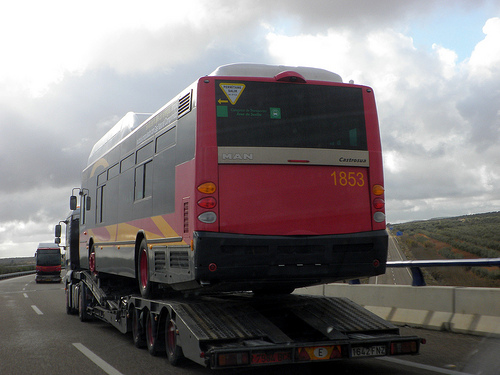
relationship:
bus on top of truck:
[70, 62, 389, 299] [53, 206, 425, 370]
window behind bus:
[213, 80, 369, 168] [70, 62, 389, 299]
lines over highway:
[21, 281, 124, 375] [0, 271, 499, 375]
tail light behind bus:
[196, 182, 217, 224] [70, 62, 389, 299]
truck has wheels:
[53, 206, 425, 370] [66, 282, 183, 367]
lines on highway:
[21, 281, 124, 375] [0, 271, 499, 375]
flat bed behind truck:
[76, 269, 426, 370] [53, 206, 425, 370]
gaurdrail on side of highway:
[291, 257, 500, 338] [0, 271, 499, 375]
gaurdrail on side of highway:
[385, 259, 499, 268] [0, 271, 499, 375]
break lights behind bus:
[371, 184, 384, 223] [70, 62, 389, 299]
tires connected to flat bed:
[131, 310, 180, 365] [76, 269, 426, 370]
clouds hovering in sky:
[0, 1, 499, 242] [0, 1, 498, 259]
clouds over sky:
[0, 1, 499, 242] [0, 1, 498, 259]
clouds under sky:
[0, 1, 499, 242] [0, 1, 498, 259]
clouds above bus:
[0, 1, 499, 242] [70, 62, 389, 299]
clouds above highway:
[0, 1, 499, 242] [0, 271, 499, 375]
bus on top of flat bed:
[70, 62, 389, 299] [76, 269, 426, 370]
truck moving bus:
[53, 206, 425, 370] [70, 62, 389, 299]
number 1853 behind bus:
[330, 170, 364, 189] [70, 62, 389, 299]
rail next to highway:
[386, 258, 498, 267] [0, 271, 499, 375]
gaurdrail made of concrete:
[291, 257, 500, 338] [291, 284, 499, 336]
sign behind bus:
[217, 82, 246, 105] [70, 62, 389, 299]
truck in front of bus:
[33, 243, 61, 283] [70, 62, 389, 299]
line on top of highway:
[375, 355, 470, 375] [0, 271, 499, 375]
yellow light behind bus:
[370, 183, 385, 196] [70, 62, 389, 299]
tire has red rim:
[136, 239, 151, 298] [139, 250, 148, 288]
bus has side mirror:
[70, 62, 389, 299] [69, 187, 82, 211]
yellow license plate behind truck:
[296, 345, 345, 362] [53, 206, 425, 370]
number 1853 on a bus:
[330, 170, 364, 189] [49, 80, 409, 317]